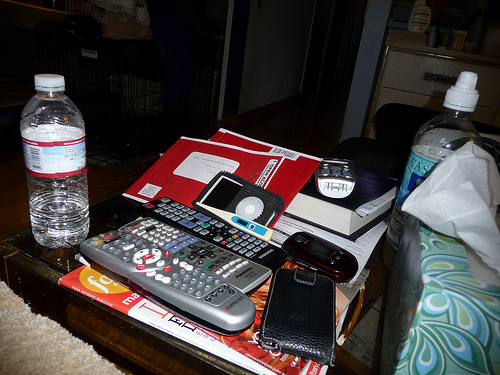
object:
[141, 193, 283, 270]
remote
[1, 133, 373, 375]
table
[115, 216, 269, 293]
remote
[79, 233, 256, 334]
remote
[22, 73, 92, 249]
water bottle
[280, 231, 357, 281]
cellphone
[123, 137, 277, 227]
letters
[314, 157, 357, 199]
remote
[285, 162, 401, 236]
book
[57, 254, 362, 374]
magazine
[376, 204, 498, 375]
tissue box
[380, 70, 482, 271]
bottle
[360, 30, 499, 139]
dresser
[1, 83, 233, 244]
floor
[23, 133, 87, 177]
label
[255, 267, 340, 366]
wallet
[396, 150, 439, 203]
label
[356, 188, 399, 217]
paper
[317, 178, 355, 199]
edges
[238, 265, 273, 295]
sharp edge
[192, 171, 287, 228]
ipod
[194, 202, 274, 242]
thermometer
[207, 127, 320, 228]
mail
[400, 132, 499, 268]
tissues